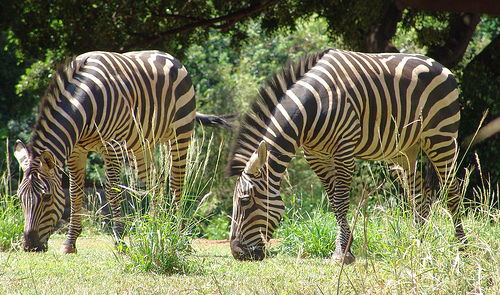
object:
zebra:
[13, 48, 197, 255]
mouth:
[25, 241, 46, 252]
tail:
[196, 111, 239, 129]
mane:
[27, 52, 85, 166]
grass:
[0, 137, 24, 249]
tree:
[256, 0, 500, 211]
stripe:
[289, 83, 318, 143]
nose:
[231, 241, 244, 259]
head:
[227, 171, 284, 261]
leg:
[170, 125, 192, 210]